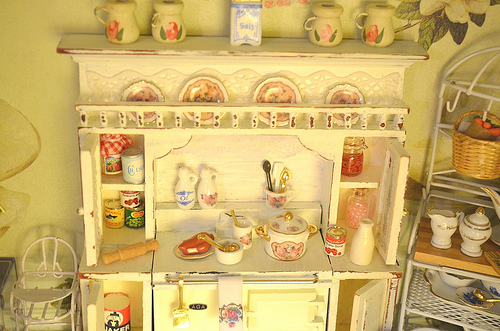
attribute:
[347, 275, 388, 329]
door — open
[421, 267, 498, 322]
platter — fine china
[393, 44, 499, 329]
metal shelf — white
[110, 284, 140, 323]
box — oatmeal, old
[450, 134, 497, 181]
basket — tan, wicker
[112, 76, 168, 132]
plate — miniature 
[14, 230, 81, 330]
chair — white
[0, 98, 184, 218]
wall — pictured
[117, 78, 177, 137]
plate — miniature 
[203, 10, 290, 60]
container — white, blue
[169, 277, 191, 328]
paint brush — gold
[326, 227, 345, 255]
can — red, white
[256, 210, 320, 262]
piece — white china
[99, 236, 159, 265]
pin — miniature 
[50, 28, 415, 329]
dollhouse cupboard — miniature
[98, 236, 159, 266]
rolling pin — wood